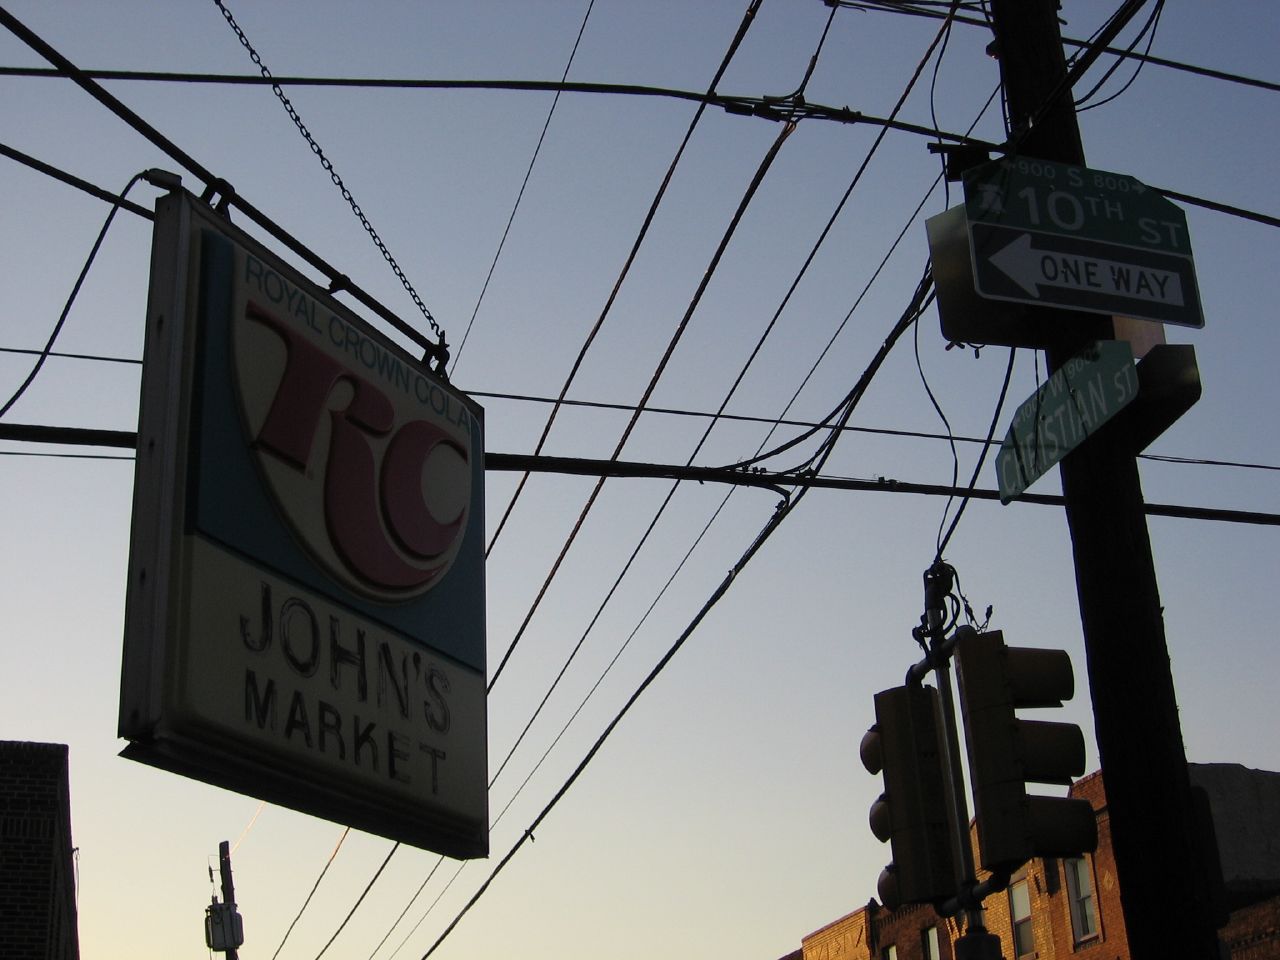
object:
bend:
[741, 388, 857, 476]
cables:
[680, 389, 853, 582]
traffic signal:
[822, 532, 1139, 954]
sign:
[161, 202, 488, 859]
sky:
[572, 580, 796, 876]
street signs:
[932, 191, 1206, 512]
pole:
[1060, 484, 1198, 912]